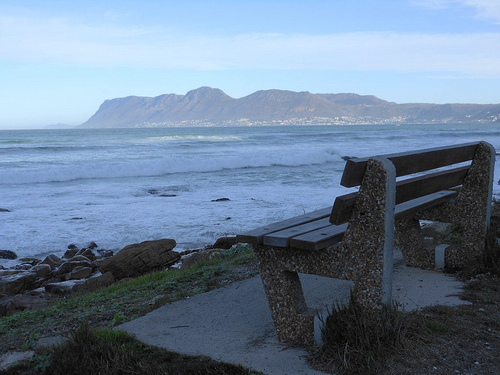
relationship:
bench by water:
[238, 133, 498, 362] [14, 116, 243, 222]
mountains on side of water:
[43, 86, 500, 129] [110, 117, 293, 213]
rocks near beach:
[6, 240, 170, 292] [1, 229, 247, 294]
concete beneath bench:
[110, 219, 475, 375] [238, 133, 498, 362]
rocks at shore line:
[0, 239, 182, 317] [15, 82, 306, 357]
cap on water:
[146, 134, 240, 144] [2, 126, 498, 266]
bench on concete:
[238, 133, 498, 362] [110, 219, 475, 375]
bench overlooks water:
[238, 133, 498, 362] [49, 138, 158, 160]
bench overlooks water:
[238, 133, 498, 362] [241, 170, 298, 197]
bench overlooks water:
[238, 133, 498, 362] [1, 122, 498, 223]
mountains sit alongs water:
[93, 79, 495, 126] [28, 127, 358, 223]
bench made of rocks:
[238, 133, 498, 362] [272, 274, 310, 356]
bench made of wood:
[238, 133, 498, 362] [358, 184, 395, 294]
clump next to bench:
[0, 238, 181, 318] [223, 130, 477, 348]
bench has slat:
[235, 140, 495, 347] [328, 162, 473, 225]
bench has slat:
[235, 140, 495, 347] [336, 142, 480, 186]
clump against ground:
[0, 225, 189, 292] [5, 251, 266, 368]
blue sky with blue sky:
[21, 2, 474, 86] [0, 0, 500, 131]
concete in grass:
[111, 231, 482, 372] [91, 273, 271, 304]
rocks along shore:
[0, 239, 182, 317] [0, 226, 338, 359]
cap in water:
[148, 135, 246, 140] [2, 126, 498, 266]